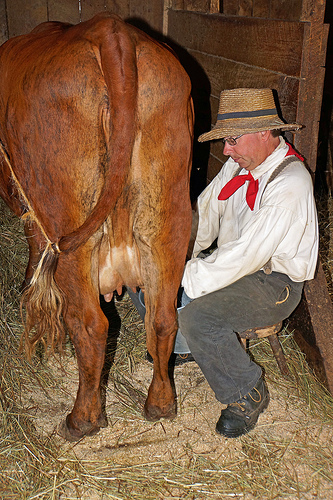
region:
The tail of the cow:
[114, 46, 129, 143]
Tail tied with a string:
[47, 243, 60, 252]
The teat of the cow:
[106, 295, 111, 301]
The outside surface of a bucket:
[177, 342, 184, 351]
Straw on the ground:
[3, 259, 14, 307]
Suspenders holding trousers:
[265, 266, 271, 272]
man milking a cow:
[151, 87, 286, 420]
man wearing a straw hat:
[179, 91, 289, 441]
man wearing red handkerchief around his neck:
[175, 69, 303, 419]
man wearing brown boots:
[176, 72, 281, 438]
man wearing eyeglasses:
[185, 85, 299, 419]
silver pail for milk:
[135, 284, 197, 355]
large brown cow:
[13, 29, 220, 426]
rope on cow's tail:
[3, 158, 75, 262]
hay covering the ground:
[12, 319, 316, 492]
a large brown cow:
[0, 11, 205, 454]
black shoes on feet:
[207, 376, 281, 448]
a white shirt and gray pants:
[188, 136, 309, 420]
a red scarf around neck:
[206, 132, 304, 221]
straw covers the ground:
[5, 207, 331, 494]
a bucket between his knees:
[137, 288, 215, 378]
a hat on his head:
[190, 83, 304, 151]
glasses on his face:
[223, 134, 253, 147]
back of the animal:
[23, 37, 248, 265]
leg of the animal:
[33, 298, 128, 422]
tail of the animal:
[0, 76, 135, 290]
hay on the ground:
[12, 440, 71, 496]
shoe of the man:
[187, 366, 284, 462]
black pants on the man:
[176, 269, 305, 399]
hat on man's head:
[198, 79, 303, 149]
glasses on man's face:
[206, 129, 245, 163]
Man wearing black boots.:
[222, 390, 260, 449]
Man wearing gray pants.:
[208, 335, 234, 369]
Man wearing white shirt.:
[233, 220, 269, 257]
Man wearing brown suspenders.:
[259, 170, 278, 193]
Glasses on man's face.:
[218, 134, 243, 148]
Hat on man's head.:
[210, 93, 275, 143]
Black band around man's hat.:
[217, 103, 278, 127]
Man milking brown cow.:
[90, 181, 196, 308]